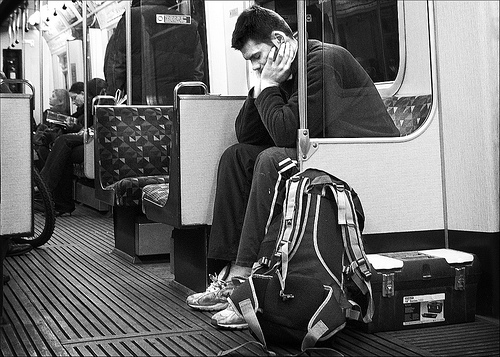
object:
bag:
[227, 167, 374, 348]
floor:
[0, 211, 500, 357]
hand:
[260, 44, 290, 82]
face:
[243, 40, 270, 76]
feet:
[187, 266, 253, 309]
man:
[179, 4, 404, 332]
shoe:
[184, 272, 251, 311]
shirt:
[234, 42, 401, 146]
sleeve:
[252, 86, 317, 149]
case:
[362, 247, 477, 333]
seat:
[111, 96, 188, 205]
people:
[33, 88, 72, 153]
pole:
[293, 0, 306, 171]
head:
[234, 8, 289, 76]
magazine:
[43, 111, 78, 128]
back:
[94, 107, 171, 184]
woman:
[45, 86, 70, 125]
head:
[49, 90, 63, 106]